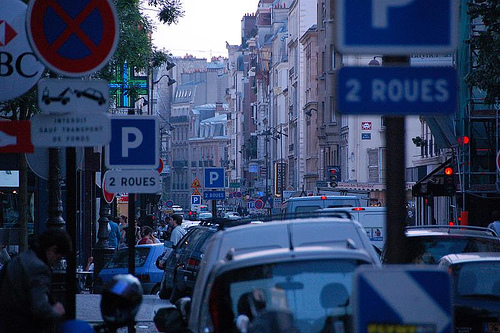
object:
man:
[3, 227, 70, 332]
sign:
[33, 112, 112, 143]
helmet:
[100, 274, 142, 318]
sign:
[108, 117, 158, 166]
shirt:
[0, 253, 59, 319]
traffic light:
[442, 162, 457, 178]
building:
[286, 10, 305, 194]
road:
[155, 204, 499, 331]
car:
[110, 245, 166, 298]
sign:
[190, 177, 201, 190]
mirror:
[210, 249, 371, 331]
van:
[185, 218, 380, 331]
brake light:
[353, 205, 365, 212]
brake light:
[318, 196, 328, 204]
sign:
[106, 171, 159, 191]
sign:
[23, 3, 119, 79]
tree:
[0, 1, 187, 126]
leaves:
[125, 19, 148, 66]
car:
[183, 218, 200, 226]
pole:
[127, 189, 135, 328]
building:
[244, 44, 281, 167]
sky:
[138, 0, 263, 52]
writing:
[120, 128, 142, 157]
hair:
[38, 229, 70, 258]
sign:
[37, 79, 111, 113]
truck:
[42, 84, 74, 108]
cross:
[110, 59, 149, 109]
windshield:
[110, 248, 150, 267]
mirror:
[156, 306, 187, 332]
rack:
[227, 242, 359, 252]